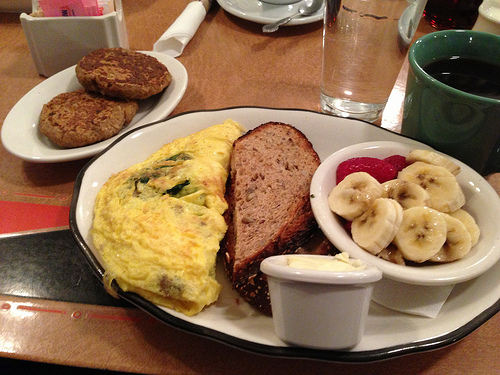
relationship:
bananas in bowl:
[344, 163, 471, 258] [309, 141, 484, 283]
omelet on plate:
[85, 121, 235, 294] [65, 100, 473, 370]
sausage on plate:
[31, 49, 174, 143] [1, 42, 181, 172]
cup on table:
[400, 23, 499, 158] [6, 12, 473, 367]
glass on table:
[311, 2, 393, 126] [6, 12, 473, 367]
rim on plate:
[417, 29, 496, 97] [65, 100, 473, 370]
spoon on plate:
[262, 0, 323, 40] [65, 100, 473, 370]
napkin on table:
[156, 2, 217, 51] [6, 12, 473, 367]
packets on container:
[33, 1, 104, 19] [18, 1, 141, 76]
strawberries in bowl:
[338, 153, 400, 177] [313, 136, 479, 297]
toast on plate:
[231, 100, 321, 271] [65, 100, 473, 370]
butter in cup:
[282, 253, 354, 280] [260, 250, 375, 359]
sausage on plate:
[31, 49, 174, 143] [6, 45, 189, 165]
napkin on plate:
[156, 2, 217, 51] [5, 46, 198, 192]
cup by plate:
[400, 29, 499, 174] [65, 100, 473, 370]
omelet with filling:
[85, 121, 235, 294] [128, 148, 201, 214]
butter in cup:
[288, 251, 365, 271] [400, 23, 499, 158]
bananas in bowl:
[328, 148, 480, 263] [258, 0, 301, 11]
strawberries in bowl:
[336, 156, 397, 183] [258, 0, 301, 11]